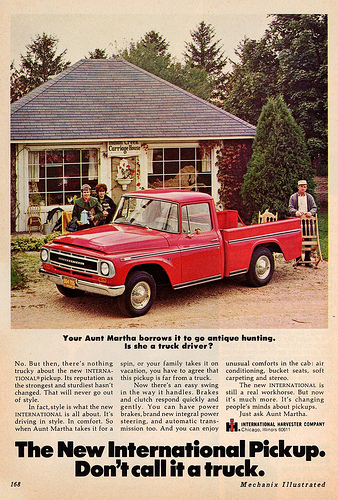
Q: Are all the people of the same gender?
A: No, they are both male and female.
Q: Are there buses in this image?
A: No, there are no buses.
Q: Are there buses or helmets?
A: No, there are no buses or helmets.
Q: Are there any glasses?
A: No, there are no glasses.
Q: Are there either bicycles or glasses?
A: No, there are no glasses or bicycles.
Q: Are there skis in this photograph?
A: No, there are no skis.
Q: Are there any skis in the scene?
A: No, there are no skis.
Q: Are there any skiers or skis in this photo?
A: No, there are no skis or skiers.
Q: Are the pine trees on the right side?
A: Yes, the pine trees are on the right of the image.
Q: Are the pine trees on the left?
A: No, the pine trees are on the right of the image.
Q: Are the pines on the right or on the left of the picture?
A: The pines are on the right of the image.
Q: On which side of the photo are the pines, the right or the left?
A: The pines are on the right of the image.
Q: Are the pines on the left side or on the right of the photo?
A: The pines are on the right of the image.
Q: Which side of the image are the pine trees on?
A: The pine trees are on the right of the image.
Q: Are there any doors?
A: Yes, there is a door.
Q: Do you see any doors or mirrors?
A: Yes, there is a door.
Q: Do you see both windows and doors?
A: Yes, there are both a door and a window.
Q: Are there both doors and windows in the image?
A: Yes, there are both a door and a window.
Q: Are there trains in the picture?
A: No, there are no trains.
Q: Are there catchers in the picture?
A: No, there are no catchers.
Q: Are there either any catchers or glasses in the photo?
A: No, there are no catchers or glasses.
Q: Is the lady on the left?
A: Yes, the lady is on the left of the image.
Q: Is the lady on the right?
A: No, the lady is on the left of the image.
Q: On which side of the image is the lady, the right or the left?
A: The lady is on the left of the image.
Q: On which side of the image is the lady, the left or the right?
A: The lady is on the left of the image.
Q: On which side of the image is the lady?
A: The lady is on the left of the image.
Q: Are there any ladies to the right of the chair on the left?
A: Yes, there is a lady to the right of the chair.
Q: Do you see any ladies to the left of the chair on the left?
A: No, the lady is to the right of the chair.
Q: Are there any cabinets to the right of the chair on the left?
A: No, there is a lady to the right of the chair.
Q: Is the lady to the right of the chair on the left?
A: Yes, the lady is to the right of the chair.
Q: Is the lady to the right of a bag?
A: No, the lady is to the right of the chair.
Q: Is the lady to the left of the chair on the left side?
A: No, the lady is to the right of the chair.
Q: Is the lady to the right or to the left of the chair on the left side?
A: The lady is to the right of the chair.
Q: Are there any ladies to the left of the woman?
A: Yes, there is a lady to the left of the woman.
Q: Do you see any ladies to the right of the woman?
A: No, the lady is to the left of the woman.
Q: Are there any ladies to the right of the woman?
A: No, the lady is to the left of the woman.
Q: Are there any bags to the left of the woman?
A: No, there is a lady to the left of the woman.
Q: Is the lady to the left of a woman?
A: Yes, the lady is to the left of a woman.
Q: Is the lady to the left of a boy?
A: No, the lady is to the left of a woman.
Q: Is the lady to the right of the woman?
A: No, the lady is to the left of the woman.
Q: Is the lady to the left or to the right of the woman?
A: The lady is to the left of the woman.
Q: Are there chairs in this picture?
A: Yes, there is a chair.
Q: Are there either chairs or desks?
A: Yes, there is a chair.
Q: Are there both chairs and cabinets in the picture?
A: No, there is a chair but no cabinets.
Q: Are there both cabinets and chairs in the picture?
A: No, there is a chair but no cabinets.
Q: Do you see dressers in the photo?
A: No, there are no dressers.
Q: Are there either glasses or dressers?
A: No, there are no dressers or glasses.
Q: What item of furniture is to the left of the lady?
A: The piece of furniture is a chair.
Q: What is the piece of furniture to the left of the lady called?
A: The piece of furniture is a chair.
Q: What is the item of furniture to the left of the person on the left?
A: The piece of furniture is a chair.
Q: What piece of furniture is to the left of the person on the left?
A: The piece of furniture is a chair.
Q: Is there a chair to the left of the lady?
A: Yes, there is a chair to the left of the lady.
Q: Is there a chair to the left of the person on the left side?
A: Yes, there is a chair to the left of the lady.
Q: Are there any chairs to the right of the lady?
A: No, the chair is to the left of the lady.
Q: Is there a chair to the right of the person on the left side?
A: No, the chair is to the left of the lady.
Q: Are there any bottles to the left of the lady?
A: No, there is a chair to the left of the lady.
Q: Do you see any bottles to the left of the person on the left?
A: No, there is a chair to the left of the lady.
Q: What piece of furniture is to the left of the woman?
A: The piece of furniture is a chair.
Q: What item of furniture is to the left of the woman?
A: The piece of furniture is a chair.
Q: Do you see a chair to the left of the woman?
A: Yes, there is a chair to the left of the woman.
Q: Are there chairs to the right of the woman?
A: No, the chair is to the left of the woman.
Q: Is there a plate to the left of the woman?
A: No, there is a chair to the left of the woman.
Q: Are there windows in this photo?
A: Yes, there is a window.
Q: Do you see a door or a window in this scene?
A: Yes, there is a window.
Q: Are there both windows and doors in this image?
A: Yes, there are both a window and a door.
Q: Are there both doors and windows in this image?
A: Yes, there are both a window and a door.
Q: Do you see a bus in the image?
A: No, there are no buses.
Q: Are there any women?
A: Yes, there is a woman.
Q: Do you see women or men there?
A: Yes, there is a woman.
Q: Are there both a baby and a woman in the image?
A: No, there is a woman but no babies.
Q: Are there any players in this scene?
A: No, there are no players.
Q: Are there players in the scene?
A: No, there are no players.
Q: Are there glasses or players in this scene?
A: No, there are no players or glasses.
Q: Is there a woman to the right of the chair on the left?
A: Yes, there is a woman to the right of the chair.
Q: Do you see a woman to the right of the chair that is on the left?
A: Yes, there is a woman to the right of the chair.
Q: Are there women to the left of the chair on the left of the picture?
A: No, the woman is to the right of the chair.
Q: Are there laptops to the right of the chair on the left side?
A: No, there is a woman to the right of the chair.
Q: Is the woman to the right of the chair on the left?
A: Yes, the woman is to the right of the chair.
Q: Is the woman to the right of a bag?
A: No, the woman is to the right of the chair.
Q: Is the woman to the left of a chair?
A: No, the woman is to the right of a chair.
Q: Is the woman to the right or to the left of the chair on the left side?
A: The woman is to the right of the chair.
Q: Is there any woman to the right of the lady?
A: Yes, there is a woman to the right of the lady.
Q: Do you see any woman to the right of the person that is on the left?
A: Yes, there is a woman to the right of the lady.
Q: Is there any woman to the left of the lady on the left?
A: No, the woman is to the right of the lady.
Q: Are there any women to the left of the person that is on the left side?
A: No, the woman is to the right of the lady.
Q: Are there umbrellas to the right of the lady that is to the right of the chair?
A: No, there is a woman to the right of the lady.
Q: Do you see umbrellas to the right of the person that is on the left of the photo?
A: No, there is a woman to the right of the lady.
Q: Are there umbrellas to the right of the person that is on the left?
A: No, there is a woman to the right of the lady.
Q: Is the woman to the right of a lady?
A: Yes, the woman is to the right of a lady.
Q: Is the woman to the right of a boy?
A: No, the woman is to the right of a lady.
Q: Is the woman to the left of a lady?
A: No, the woman is to the right of a lady.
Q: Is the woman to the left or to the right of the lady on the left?
A: The woman is to the right of the lady.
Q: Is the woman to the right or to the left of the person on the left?
A: The woman is to the right of the lady.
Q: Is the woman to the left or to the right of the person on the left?
A: The woman is to the right of the lady.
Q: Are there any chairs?
A: Yes, there is a chair.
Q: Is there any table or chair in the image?
A: Yes, there is a chair.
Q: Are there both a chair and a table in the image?
A: No, there is a chair but no tables.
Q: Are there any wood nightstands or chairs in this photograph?
A: Yes, there is a wood chair.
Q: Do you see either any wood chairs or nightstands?
A: Yes, there is a wood chair.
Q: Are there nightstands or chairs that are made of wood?
A: Yes, the chair is made of wood.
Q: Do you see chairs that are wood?
A: Yes, there is a wood chair.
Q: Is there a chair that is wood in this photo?
A: Yes, there is a wood chair.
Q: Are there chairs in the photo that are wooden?
A: Yes, there is a chair that is wooden.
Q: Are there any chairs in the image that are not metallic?
A: Yes, there is a wooden chair.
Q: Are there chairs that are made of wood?
A: Yes, there is a chair that is made of wood.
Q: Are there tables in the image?
A: No, there are no tables.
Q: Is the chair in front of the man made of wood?
A: Yes, the chair is made of wood.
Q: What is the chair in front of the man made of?
A: The chair is made of wood.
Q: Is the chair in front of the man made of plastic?
A: No, the chair is made of wood.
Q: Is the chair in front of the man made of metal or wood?
A: The chair is made of wood.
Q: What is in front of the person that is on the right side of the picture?
A: The chair is in front of the man.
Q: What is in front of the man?
A: The chair is in front of the man.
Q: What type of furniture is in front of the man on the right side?
A: The piece of furniture is a chair.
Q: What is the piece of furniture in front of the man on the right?
A: The piece of furniture is a chair.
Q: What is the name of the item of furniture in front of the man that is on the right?
A: The piece of furniture is a chair.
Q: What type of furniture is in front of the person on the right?
A: The piece of furniture is a chair.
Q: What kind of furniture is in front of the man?
A: The piece of furniture is a chair.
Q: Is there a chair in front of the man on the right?
A: Yes, there is a chair in front of the man.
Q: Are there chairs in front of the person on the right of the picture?
A: Yes, there is a chair in front of the man.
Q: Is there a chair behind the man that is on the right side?
A: No, the chair is in front of the man.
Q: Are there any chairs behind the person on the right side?
A: No, the chair is in front of the man.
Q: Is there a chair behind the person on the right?
A: No, the chair is in front of the man.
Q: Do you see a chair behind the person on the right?
A: No, the chair is in front of the man.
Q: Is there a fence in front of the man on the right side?
A: No, there is a chair in front of the man.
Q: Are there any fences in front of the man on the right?
A: No, there is a chair in front of the man.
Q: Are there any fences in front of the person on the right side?
A: No, there is a chair in front of the man.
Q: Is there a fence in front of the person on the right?
A: No, there is a chair in front of the man.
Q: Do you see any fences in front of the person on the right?
A: No, there is a chair in front of the man.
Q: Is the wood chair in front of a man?
A: Yes, the chair is in front of a man.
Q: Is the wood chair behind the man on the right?
A: No, the chair is in front of the man.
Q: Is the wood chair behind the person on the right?
A: No, the chair is in front of the man.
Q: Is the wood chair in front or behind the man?
A: The chair is in front of the man.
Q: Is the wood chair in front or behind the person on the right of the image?
A: The chair is in front of the man.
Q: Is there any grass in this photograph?
A: Yes, there is grass.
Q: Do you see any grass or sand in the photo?
A: Yes, there is grass.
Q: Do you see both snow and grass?
A: No, there is grass but no snow.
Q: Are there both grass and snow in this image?
A: No, there is grass but no snow.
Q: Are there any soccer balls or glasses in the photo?
A: No, there are no glasses or soccer balls.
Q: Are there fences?
A: No, there are no fences.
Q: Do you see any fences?
A: No, there are no fences.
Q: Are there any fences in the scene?
A: No, there are no fences.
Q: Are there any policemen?
A: No, there are no policemen.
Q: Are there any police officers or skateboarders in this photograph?
A: No, there are no police officers or skateboarders.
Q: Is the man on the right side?
A: Yes, the man is on the right of the image.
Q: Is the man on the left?
A: No, the man is on the right of the image.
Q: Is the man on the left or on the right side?
A: The man is on the right of the image.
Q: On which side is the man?
A: The man is on the right of the image.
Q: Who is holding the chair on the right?
A: The man is holding the chair.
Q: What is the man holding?
A: The man is holding the chair.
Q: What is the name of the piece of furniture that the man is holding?
A: The piece of furniture is a chair.